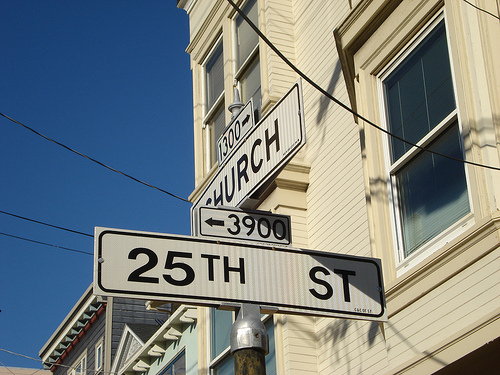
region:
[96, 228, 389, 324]
black and white street sign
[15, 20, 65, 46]
white clouds in blue sky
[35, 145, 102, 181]
white clouds in blue sky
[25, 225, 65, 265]
white clouds in blue sky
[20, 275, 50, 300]
white clouds in blue sky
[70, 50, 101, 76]
white clouds in blue sky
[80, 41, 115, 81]
white clouds in blue sky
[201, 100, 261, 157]
black and white street sign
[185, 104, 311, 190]
black and white street sign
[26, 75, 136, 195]
the sky is clear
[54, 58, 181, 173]
the sky is clear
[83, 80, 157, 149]
the sky is clear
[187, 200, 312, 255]
the number is 3900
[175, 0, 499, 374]
a large white building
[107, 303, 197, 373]
a light blue building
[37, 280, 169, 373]
a gray building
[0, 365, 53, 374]
a building in the background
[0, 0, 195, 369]
a large area of blue sky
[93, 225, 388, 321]
street sign on the bottom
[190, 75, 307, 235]
street sign on the top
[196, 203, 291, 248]
address sign on the bottom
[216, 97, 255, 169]
address sign on the top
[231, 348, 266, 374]
a sign post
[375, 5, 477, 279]
Window on side of building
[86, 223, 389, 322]
White street sign on pole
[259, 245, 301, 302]
Grey lines on white sign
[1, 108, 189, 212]
Black power line next to building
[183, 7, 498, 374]
Building with yellow siding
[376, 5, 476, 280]
Window with white trim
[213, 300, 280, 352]
Metal holder attached to sign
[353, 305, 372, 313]
Numbers in corner of sign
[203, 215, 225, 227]
Black arrow on side of sign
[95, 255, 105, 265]
Silver rivot on side of sign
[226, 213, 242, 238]
The number is black.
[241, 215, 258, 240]
The number is black.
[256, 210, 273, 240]
The number is black.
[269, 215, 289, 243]
The number is black.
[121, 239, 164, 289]
The number is black.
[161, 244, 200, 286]
The number is black.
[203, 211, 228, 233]
The arrow is black.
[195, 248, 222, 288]
The letter is black.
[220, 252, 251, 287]
The letter is black.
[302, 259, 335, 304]
The letter is black.